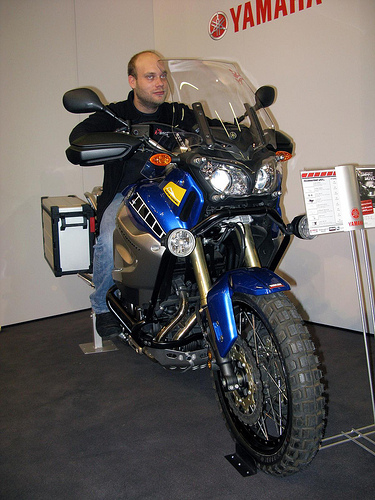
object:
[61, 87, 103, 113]
mirror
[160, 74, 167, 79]
eyes open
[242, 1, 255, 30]
letter a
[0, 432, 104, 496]
ground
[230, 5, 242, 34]
letters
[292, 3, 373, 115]
wall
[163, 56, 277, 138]
window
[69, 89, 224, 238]
jacket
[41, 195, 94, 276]
box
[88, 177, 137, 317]
jeans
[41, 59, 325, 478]
bike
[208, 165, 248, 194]
front lights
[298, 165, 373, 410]
stand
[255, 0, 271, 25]
letter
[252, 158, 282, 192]
headlight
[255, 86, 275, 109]
mirror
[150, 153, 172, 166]
light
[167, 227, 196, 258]
light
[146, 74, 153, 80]
eyes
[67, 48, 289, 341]
man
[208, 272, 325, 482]
tire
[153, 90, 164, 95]
mouth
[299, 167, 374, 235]
catalog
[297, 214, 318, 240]
light